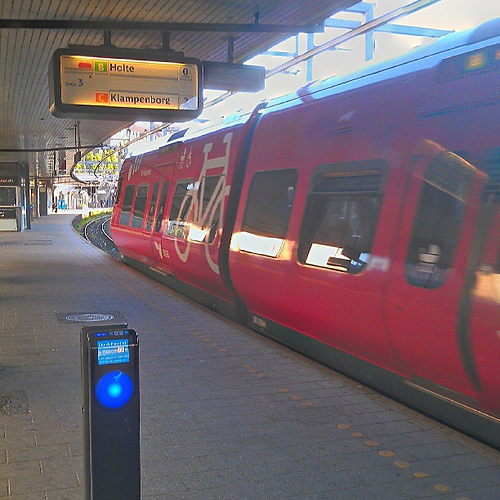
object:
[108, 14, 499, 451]
train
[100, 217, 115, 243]
track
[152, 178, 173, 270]
train door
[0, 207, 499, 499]
platform